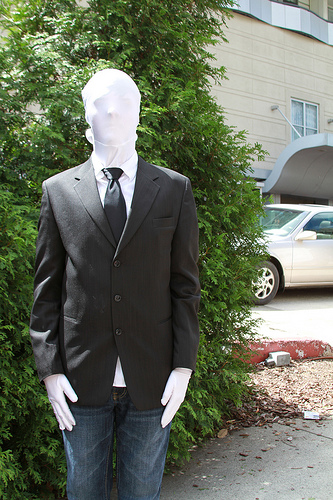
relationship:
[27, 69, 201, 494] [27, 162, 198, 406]
man wears suit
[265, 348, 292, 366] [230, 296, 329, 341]
box by driveway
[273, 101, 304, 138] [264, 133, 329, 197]
pole holds awning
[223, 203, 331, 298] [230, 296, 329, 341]
car in driveway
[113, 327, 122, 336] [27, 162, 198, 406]
button on suit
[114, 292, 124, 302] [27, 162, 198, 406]
button on suit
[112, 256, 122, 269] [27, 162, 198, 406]
button on suit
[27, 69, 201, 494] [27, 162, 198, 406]
man in suit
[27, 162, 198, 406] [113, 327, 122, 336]
suit has button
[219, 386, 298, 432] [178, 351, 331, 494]
leaves on ground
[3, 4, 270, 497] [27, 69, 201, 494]
bush behind man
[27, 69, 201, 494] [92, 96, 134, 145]
man has face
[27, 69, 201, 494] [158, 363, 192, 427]
man wears glove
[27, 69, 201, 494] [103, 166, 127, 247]
man wears tie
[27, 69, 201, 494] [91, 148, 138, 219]
man wears shirt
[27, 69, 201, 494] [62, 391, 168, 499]
man wears jeans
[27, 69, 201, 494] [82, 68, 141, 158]
man wears mask